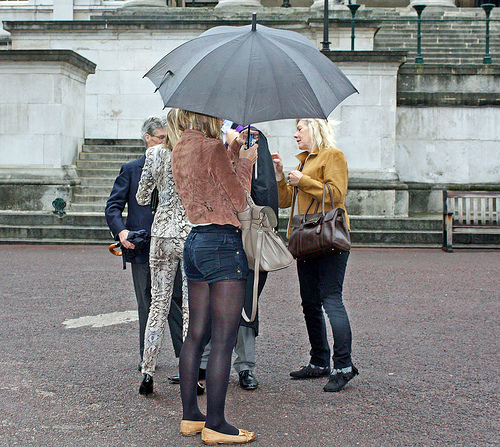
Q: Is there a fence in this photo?
A: No, there are no fences.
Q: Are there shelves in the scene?
A: No, there are no shelves.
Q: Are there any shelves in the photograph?
A: No, there are no shelves.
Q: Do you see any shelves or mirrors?
A: No, there are no shelves or mirrors.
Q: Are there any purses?
A: Yes, there is a purse.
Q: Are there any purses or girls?
A: Yes, there is a purse.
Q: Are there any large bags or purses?
A: Yes, there is a large purse.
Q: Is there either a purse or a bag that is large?
A: Yes, the purse is large.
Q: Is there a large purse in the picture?
A: Yes, there is a large purse.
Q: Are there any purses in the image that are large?
A: Yes, there is a purse that is large.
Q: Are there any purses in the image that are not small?
A: Yes, there is a large purse.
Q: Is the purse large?
A: Yes, the purse is large.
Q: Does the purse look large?
A: Yes, the purse is large.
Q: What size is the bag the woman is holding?
A: The purse is large.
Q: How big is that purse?
A: The purse is large.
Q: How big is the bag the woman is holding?
A: The purse is large.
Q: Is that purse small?
A: No, the purse is large.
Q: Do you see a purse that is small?
A: No, there is a purse but it is large.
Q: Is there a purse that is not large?
A: No, there is a purse but it is large.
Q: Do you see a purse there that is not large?
A: No, there is a purse but it is large.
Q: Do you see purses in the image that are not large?
A: No, there is a purse but it is large.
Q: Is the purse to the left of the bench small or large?
A: The purse is large.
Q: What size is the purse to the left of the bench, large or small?
A: The purse is large.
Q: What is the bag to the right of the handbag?
A: The bag is a purse.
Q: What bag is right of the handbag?
A: The bag is a purse.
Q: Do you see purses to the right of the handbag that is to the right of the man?
A: Yes, there is a purse to the right of the handbag.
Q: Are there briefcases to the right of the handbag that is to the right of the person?
A: No, there is a purse to the right of the handbag.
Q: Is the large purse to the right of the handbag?
A: Yes, the purse is to the right of the handbag.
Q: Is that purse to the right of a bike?
A: No, the purse is to the right of the handbag.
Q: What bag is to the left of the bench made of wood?
A: The bag is a purse.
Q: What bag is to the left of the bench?
A: The bag is a purse.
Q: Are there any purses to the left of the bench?
A: Yes, there is a purse to the left of the bench.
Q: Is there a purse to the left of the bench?
A: Yes, there is a purse to the left of the bench.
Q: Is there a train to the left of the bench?
A: No, there is a purse to the left of the bench.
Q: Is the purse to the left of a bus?
A: No, the purse is to the left of a bench.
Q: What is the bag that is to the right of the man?
A: The bag is a purse.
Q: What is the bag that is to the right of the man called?
A: The bag is a purse.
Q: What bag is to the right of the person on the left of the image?
A: The bag is a purse.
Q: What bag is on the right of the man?
A: The bag is a purse.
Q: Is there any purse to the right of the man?
A: Yes, there is a purse to the right of the man.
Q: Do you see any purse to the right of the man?
A: Yes, there is a purse to the right of the man.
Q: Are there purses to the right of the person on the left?
A: Yes, there is a purse to the right of the man.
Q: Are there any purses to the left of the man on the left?
A: No, the purse is to the right of the man.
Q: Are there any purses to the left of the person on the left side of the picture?
A: No, the purse is to the right of the man.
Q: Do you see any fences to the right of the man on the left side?
A: No, there is a purse to the right of the man.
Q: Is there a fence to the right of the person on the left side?
A: No, there is a purse to the right of the man.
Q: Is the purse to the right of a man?
A: Yes, the purse is to the right of a man.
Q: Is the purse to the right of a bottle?
A: No, the purse is to the right of a man.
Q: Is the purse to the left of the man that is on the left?
A: No, the purse is to the right of the man.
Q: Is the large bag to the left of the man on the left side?
A: No, the purse is to the right of the man.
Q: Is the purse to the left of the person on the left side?
A: No, the purse is to the right of the man.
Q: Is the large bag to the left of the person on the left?
A: No, the purse is to the right of the man.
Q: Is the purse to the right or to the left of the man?
A: The purse is to the right of the man.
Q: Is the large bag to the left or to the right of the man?
A: The purse is to the right of the man.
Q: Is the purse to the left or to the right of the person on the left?
A: The purse is to the right of the man.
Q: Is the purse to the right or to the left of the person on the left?
A: The purse is to the right of the man.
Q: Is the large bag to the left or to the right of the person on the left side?
A: The purse is to the right of the man.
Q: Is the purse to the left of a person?
A: No, the purse is to the right of a person.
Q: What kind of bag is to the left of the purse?
A: The bag is a handbag.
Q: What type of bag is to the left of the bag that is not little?
A: The bag is a handbag.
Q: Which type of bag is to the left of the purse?
A: The bag is a handbag.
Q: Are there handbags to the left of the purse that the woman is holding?
A: Yes, there is a handbag to the left of the purse.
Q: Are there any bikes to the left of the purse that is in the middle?
A: No, there is a handbag to the left of the purse.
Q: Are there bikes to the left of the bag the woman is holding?
A: No, there is a handbag to the left of the purse.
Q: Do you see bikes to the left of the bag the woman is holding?
A: No, there is a handbag to the left of the purse.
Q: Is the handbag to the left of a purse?
A: Yes, the handbag is to the left of a purse.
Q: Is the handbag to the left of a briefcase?
A: No, the handbag is to the left of a purse.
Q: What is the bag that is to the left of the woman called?
A: The bag is a handbag.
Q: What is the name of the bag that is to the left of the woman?
A: The bag is a handbag.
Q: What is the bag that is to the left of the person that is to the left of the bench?
A: The bag is a handbag.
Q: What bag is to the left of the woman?
A: The bag is a handbag.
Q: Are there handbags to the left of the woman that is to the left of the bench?
A: Yes, there is a handbag to the left of the woman.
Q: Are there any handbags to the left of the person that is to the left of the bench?
A: Yes, there is a handbag to the left of the woman.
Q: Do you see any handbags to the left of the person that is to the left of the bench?
A: Yes, there is a handbag to the left of the woman.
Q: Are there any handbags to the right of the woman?
A: No, the handbag is to the left of the woman.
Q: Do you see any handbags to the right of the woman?
A: No, the handbag is to the left of the woman.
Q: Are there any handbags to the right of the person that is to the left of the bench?
A: No, the handbag is to the left of the woman.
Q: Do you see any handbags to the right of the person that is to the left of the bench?
A: No, the handbag is to the left of the woman.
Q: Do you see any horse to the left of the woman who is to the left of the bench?
A: No, there is a handbag to the left of the woman.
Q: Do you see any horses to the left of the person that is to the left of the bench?
A: No, there is a handbag to the left of the woman.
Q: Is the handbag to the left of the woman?
A: Yes, the handbag is to the left of the woman.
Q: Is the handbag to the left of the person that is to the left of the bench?
A: Yes, the handbag is to the left of the woman.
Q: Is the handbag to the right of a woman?
A: No, the handbag is to the left of a woman.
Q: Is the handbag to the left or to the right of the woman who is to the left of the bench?
A: The handbag is to the left of the woman.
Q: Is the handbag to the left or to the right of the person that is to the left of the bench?
A: The handbag is to the left of the woman.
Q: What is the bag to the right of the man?
A: The bag is a handbag.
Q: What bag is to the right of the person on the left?
A: The bag is a handbag.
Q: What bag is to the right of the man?
A: The bag is a handbag.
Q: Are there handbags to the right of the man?
A: Yes, there is a handbag to the right of the man.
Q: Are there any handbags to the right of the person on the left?
A: Yes, there is a handbag to the right of the man.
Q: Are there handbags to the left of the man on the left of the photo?
A: No, the handbag is to the right of the man.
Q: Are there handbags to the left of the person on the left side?
A: No, the handbag is to the right of the man.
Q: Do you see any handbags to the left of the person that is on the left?
A: No, the handbag is to the right of the man.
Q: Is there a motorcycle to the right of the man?
A: No, there is a handbag to the right of the man.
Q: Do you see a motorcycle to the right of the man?
A: No, there is a handbag to the right of the man.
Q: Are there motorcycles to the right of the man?
A: No, there is a handbag to the right of the man.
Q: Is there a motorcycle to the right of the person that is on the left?
A: No, there is a handbag to the right of the man.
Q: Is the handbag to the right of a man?
A: Yes, the handbag is to the right of a man.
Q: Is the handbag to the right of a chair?
A: No, the handbag is to the right of a man.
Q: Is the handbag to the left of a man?
A: No, the handbag is to the right of a man.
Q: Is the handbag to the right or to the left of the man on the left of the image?
A: The handbag is to the right of the man.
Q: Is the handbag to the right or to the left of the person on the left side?
A: The handbag is to the right of the man.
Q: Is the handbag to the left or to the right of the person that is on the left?
A: The handbag is to the right of the man.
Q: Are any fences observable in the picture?
A: No, there are no fences.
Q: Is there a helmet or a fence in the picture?
A: No, there are no fences or helmets.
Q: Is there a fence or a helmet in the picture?
A: No, there are no fences or helmets.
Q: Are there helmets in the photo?
A: No, there are no helmets.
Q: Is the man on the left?
A: Yes, the man is on the left of the image.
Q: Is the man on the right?
A: No, the man is on the left of the image.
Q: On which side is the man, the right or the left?
A: The man is on the left of the image.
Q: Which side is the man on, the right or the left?
A: The man is on the left of the image.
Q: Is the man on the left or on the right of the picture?
A: The man is on the left of the image.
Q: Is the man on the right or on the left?
A: The man is on the left of the image.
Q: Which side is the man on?
A: The man is on the left of the image.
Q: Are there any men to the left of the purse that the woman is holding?
A: Yes, there is a man to the left of the purse.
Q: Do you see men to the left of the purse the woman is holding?
A: Yes, there is a man to the left of the purse.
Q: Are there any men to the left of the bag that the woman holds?
A: Yes, there is a man to the left of the purse.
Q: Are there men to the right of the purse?
A: No, the man is to the left of the purse.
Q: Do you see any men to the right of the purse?
A: No, the man is to the left of the purse.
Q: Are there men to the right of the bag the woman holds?
A: No, the man is to the left of the purse.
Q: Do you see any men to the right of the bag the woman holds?
A: No, the man is to the left of the purse.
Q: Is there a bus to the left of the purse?
A: No, there is a man to the left of the purse.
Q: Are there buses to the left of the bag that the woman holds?
A: No, there is a man to the left of the purse.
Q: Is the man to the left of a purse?
A: Yes, the man is to the left of a purse.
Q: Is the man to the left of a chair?
A: No, the man is to the left of a purse.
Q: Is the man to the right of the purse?
A: No, the man is to the left of the purse.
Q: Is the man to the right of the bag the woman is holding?
A: No, the man is to the left of the purse.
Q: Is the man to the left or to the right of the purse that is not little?
A: The man is to the left of the purse.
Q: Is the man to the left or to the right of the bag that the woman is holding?
A: The man is to the left of the purse.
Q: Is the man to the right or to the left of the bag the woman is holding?
A: The man is to the left of the purse.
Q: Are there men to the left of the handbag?
A: Yes, there is a man to the left of the handbag.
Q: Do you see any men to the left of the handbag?
A: Yes, there is a man to the left of the handbag.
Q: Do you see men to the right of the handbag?
A: No, the man is to the left of the handbag.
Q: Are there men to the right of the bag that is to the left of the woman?
A: No, the man is to the left of the handbag.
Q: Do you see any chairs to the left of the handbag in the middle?
A: No, there is a man to the left of the handbag.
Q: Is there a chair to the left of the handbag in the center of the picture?
A: No, there is a man to the left of the handbag.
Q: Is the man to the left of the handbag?
A: Yes, the man is to the left of the handbag.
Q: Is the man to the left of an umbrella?
A: No, the man is to the left of the handbag.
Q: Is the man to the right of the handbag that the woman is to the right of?
A: No, the man is to the left of the handbag.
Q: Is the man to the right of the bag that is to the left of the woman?
A: No, the man is to the left of the handbag.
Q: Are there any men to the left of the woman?
A: Yes, there is a man to the left of the woman.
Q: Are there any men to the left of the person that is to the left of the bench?
A: Yes, there is a man to the left of the woman.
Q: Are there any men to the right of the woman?
A: No, the man is to the left of the woman.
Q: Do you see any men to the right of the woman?
A: No, the man is to the left of the woman.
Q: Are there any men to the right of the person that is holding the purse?
A: No, the man is to the left of the woman.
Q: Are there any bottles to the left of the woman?
A: No, there is a man to the left of the woman.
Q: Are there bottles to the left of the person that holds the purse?
A: No, there is a man to the left of the woman.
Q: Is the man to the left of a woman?
A: Yes, the man is to the left of a woman.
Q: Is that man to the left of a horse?
A: No, the man is to the left of a woman.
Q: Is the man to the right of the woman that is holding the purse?
A: No, the man is to the left of the woman.